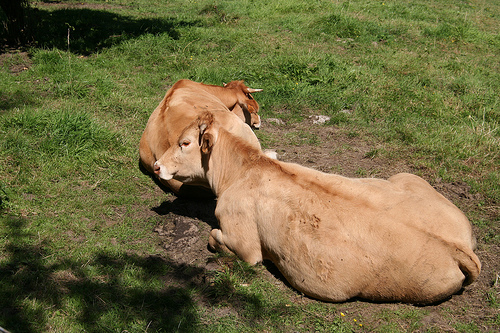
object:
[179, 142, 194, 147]
eyes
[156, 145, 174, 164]
nose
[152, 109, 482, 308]
cow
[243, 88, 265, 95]
horns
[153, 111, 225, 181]
head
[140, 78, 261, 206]
cow